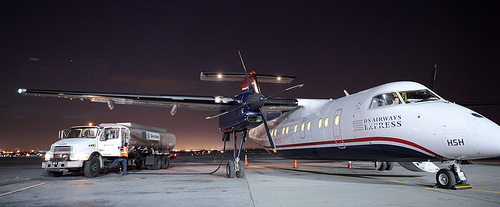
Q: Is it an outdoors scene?
A: Yes, it is outdoors.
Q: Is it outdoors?
A: Yes, it is outdoors.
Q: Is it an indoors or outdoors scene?
A: It is outdoors.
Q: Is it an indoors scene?
A: No, it is outdoors.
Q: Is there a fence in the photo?
A: No, there are no fences.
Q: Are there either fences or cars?
A: No, there are no fences or cars.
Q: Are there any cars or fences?
A: No, there are no fences or cars.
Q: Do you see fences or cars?
A: No, there are no fences or cars.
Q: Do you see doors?
A: Yes, there is a door.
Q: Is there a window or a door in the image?
A: Yes, there is a door.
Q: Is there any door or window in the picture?
A: Yes, there is a door.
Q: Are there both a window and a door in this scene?
A: Yes, there are both a door and a window.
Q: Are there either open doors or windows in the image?
A: Yes, there is an open door.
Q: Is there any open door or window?
A: Yes, there is an open door.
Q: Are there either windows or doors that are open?
A: Yes, the door is open.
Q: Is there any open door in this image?
A: Yes, there is an open door.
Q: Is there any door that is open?
A: Yes, there is a door that is open.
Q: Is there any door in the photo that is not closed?
A: Yes, there is a open door.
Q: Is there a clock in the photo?
A: No, there are no clocks.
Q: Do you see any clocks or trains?
A: No, there are no clocks or trains.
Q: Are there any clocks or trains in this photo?
A: No, there are no clocks or trains.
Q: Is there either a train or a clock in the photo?
A: No, there are no clocks or trains.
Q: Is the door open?
A: Yes, the door is open.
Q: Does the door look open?
A: Yes, the door is open.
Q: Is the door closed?
A: No, the door is open.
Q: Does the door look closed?
A: No, the door is open.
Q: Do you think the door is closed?
A: No, the door is open.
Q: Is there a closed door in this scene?
A: No, there is a door but it is open.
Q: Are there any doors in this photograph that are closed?
A: No, there is a door but it is open.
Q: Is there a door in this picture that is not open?
A: No, there is a door but it is open.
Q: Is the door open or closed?
A: The door is open.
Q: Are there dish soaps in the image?
A: No, there are no dish soaps.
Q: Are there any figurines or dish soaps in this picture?
A: No, there are no dish soaps or figurines.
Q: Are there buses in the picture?
A: No, there are no buses.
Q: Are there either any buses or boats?
A: No, there are no buses or boats.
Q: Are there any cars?
A: No, there are no cars.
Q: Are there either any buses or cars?
A: No, there are no cars or buses.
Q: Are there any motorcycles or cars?
A: No, there are no cars or motorcycles.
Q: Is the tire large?
A: Yes, the tire is large.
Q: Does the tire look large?
A: Yes, the tire is large.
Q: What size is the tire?
A: The tire is large.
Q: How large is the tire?
A: The tire is large.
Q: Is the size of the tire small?
A: No, the tire is large.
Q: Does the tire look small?
A: No, the tire is large.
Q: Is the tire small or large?
A: The tire is large.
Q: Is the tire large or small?
A: The tire is large.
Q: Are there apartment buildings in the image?
A: No, there are no apartment buildings.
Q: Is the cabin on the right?
A: Yes, the cabin is on the right of the image.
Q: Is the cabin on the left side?
A: No, the cabin is on the right of the image.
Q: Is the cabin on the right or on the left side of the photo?
A: The cabin is on the right of the image.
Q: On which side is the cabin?
A: The cabin is on the right of the image.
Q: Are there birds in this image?
A: No, there are no birds.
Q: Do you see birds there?
A: No, there are no birds.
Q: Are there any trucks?
A: Yes, there is a truck.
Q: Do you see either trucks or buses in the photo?
A: Yes, there is a truck.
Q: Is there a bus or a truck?
A: Yes, there is a truck.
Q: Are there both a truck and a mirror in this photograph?
A: No, there is a truck but no mirrors.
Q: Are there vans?
A: No, there are no vans.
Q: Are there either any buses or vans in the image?
A: No, there are no vans or buses.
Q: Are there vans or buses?
A: No, there are no vans or buses.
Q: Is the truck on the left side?
A: Yes, the truck is on the left of the image.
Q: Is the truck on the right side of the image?
A: No, the truck is on the left of the image.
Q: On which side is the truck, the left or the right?
A: The truck is on the left of the image.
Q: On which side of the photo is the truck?
A: The truck is on the left of the image.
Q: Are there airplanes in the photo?
A: Yes, there is an airplane.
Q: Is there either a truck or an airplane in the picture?
A: Yes, there is an airplane.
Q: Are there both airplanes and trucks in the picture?
A: Yes, there are both an airplane and a truck.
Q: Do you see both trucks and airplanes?
A: Yes, there are both an airplane and a truck.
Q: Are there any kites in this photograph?
A: No, there are no kites.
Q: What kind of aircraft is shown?
A: The aircraft is an airplane.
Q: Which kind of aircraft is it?
A: The aircraft is an airplane.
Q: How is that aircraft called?
A: This is an airplane.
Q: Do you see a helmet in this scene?
A: No, there are no helmets.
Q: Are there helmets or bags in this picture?
A: No, there are no helmets or bags.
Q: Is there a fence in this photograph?
A: No, there are no fences.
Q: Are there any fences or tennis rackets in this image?
A: No, there are no fences or tennis rackets.